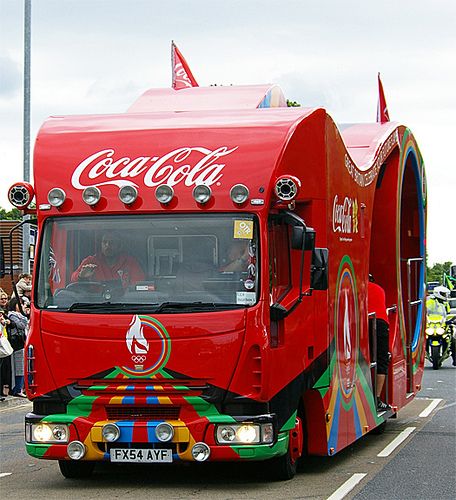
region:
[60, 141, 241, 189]
white lettering on red background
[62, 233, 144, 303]
man driving red bus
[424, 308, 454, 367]
yellow motorcycle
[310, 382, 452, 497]
white dotted line painted on road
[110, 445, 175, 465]
front license plate of red bus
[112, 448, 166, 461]
black lettering on white background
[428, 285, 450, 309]
person riding yellow motorcycle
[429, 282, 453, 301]
white helmet of person on motorcycle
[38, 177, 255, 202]
row of lights above windshield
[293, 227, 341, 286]
black sideview mirrors on red bus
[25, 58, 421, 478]
the truck is red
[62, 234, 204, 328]
man with red jacket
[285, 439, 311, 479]
part of a wheel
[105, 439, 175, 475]
License plate on the truck.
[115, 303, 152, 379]
Coca Cola is a sponsor of the Olympics.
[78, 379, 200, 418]
Brightly colored grill of the truck.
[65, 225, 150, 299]
Bus driver ready to blow the horn.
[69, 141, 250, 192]
Coca Cola would like to teach the world to sing.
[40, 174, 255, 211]
Many lights on the truck.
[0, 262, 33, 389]
Crowds watching the parade.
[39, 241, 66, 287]
British flag inside the truck.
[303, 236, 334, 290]
Large side view mirror.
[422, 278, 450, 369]
Man on a motorcycle.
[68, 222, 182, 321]
the man is driving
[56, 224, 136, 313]
the man is driving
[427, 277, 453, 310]
the helmet is white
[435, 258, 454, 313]
the helmet is white